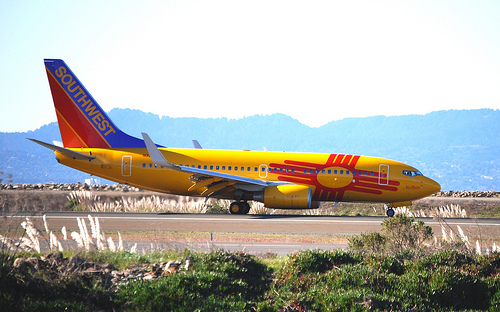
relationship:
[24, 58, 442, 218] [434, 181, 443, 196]
plane has a nose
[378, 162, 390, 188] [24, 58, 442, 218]
door of plane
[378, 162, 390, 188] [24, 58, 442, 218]
door on plane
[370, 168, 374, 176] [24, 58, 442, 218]
window on plane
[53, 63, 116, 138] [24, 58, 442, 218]
symbol on plane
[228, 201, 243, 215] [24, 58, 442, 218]
wheel on plane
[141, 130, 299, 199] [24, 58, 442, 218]
wing on plane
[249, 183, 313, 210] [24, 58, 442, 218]
engine on plane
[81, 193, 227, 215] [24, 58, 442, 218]
plant by plane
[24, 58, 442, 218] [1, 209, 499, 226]
plane on runway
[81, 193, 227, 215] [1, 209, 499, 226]
plant on runway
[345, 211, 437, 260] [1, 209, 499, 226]
shrub by runway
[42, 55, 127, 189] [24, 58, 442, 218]
tail on plane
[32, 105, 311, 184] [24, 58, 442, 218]
mountain behind plane